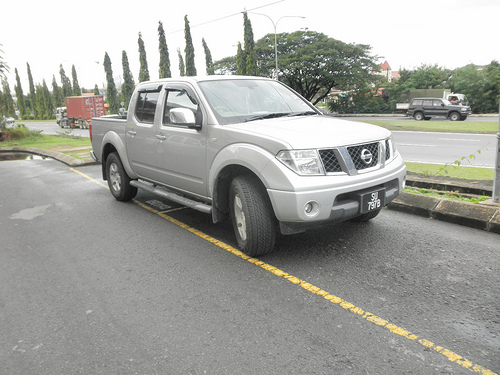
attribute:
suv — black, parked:
[403, 90, 470, 125]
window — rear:
[134, 84, 158, 135]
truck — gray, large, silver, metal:
[88, 73, 408, 257]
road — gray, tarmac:
[0, 149, 499, 373]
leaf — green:
[292, 46, 301, 56]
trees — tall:
[27, 52, 169, 83]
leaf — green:
[287, 51, 313, 68]